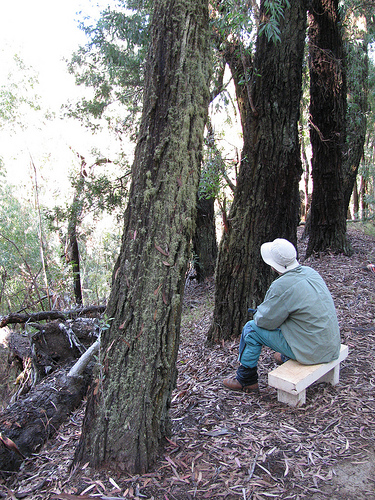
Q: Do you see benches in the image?
A: Yes, there is a bench.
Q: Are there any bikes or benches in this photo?
A: Yes, there is a bench.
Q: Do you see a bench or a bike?
A: Yes, there is a bench.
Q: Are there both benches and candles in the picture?
A: No, there is a bench but no candles.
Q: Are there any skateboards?
A: No, there are no skateboards.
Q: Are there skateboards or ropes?
A: No, there are no skateboards or ropes.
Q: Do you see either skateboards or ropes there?
A: No, there are no skateboards or ropes.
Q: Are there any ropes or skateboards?
A: No, there are no skateboards or ropes.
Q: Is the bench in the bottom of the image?
A: Yes, the bench is in the bottom of the image.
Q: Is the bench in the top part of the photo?
A: No, the bench is in the bottom of the image.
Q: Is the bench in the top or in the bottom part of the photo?
A: The bench is in the bottom of the image.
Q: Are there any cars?
A: No, there are no cars.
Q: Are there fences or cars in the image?
A: No, there are no cars or fences.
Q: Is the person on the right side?
A: Yes, the person is on the right of the image.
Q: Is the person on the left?
A: No, the person is on the right of the image.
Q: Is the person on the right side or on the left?
A: The person is on the right of the image.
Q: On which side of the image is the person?
A: The person is on the right of the image.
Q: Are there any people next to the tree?
A: Yes, there is a person next to the tree.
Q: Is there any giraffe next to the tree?
A: No, there is a person next to the tree.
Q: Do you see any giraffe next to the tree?
A: No, there is a person next to the tree.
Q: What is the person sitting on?
A: The person is sitting on the bench.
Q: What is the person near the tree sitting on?
A: The person is sitting on the bench.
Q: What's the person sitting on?
A: The person is sitting on the bench.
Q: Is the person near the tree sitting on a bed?
A: No, the person is sitting on the bench.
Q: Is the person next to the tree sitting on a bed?
A: No, the person is sitting on the bench.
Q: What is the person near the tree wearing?
A: The person is wearing a hat.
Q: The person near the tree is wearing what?
A: The person is wearing a hat.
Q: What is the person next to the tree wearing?
A: The person is wearing a hat.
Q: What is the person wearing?
A: The person is wearing a hat.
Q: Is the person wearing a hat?
A: Yes, the person is wearing a hat.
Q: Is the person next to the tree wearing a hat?
A: Yes, the person is wearing a hat.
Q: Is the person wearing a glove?
A: No, the person is wearing a hat.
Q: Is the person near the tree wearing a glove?
A: No, the person is wearing a hat.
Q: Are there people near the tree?
A: Yes, there is a person near the tree.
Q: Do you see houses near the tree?
A: No, there is a person near the tree.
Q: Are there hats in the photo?
A: Yes, there is a hat.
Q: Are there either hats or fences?
A: Yes, there is a hat.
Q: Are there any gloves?
A: No, there are no gloves.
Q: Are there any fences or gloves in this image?
A: No, there are no gloves or fences.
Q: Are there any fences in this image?
A: No, there are no fences.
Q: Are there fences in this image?
A: No, there are no fences.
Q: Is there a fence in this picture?
A: No, there are no fences.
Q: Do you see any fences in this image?
A: No, there are no fences.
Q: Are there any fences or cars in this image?
A: No, there are no fences or cars.